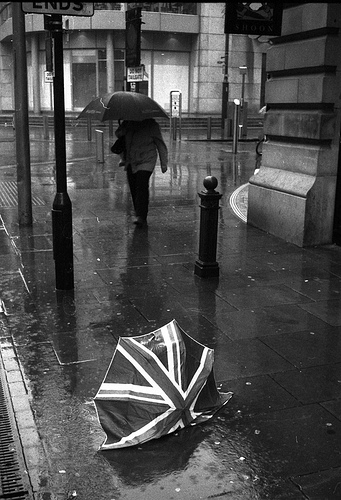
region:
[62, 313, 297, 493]
the umbrella is broken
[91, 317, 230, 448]
the umbrella is broken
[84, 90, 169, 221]
person walking in the rain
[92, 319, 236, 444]
opened umbrella on the ground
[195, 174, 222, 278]
the black post on the sidewalk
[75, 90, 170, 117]
the opened umbrella the person is carrying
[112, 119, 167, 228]
the person under the umbrella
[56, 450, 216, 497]
the puddle on the ground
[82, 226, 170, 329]
the reflection of the person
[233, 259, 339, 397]
the wet sidewalk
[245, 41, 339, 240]
the side of the building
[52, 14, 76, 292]
the black pole on the ground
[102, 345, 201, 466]
an umbrella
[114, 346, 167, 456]
an umbrella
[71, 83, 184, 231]
a person walks in the rain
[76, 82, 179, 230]
a person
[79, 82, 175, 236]
a person under an umbrella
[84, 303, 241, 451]
an umbrella on the ground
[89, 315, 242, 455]
a crumpled umbrella on the ground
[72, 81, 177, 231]
the person is carrying a black umbrella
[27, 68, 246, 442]
the person walks towards the discarded umbrella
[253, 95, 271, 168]
the edge of a bicycle can be seen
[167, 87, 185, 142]
a payphone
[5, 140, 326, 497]
the ground is wet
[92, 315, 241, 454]
Umbrella on the floor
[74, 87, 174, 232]
Woman walking holding umbrella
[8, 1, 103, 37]
Ends sign on post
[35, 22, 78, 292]
Black post on the sidewalk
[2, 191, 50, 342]
Rain on the sidewalk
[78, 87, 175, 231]
Woman walking on the sidewalk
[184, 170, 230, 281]
Black small pole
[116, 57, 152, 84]
Street white and black sign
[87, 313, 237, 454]
British design print on umbrella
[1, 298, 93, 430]
Wet sidewalk tiles